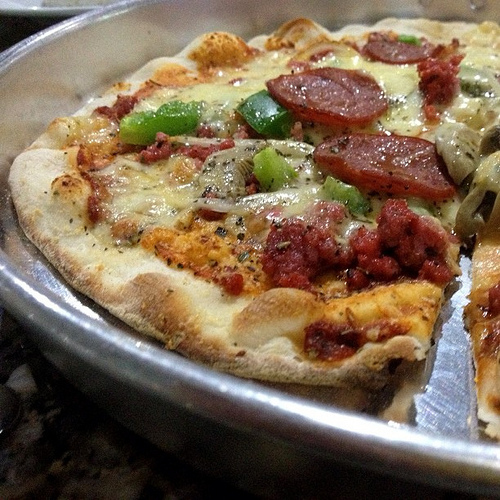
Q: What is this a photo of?
A: Pizza.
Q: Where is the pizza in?
A: Pan.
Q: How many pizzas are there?
A: 1.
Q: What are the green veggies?
A: Green peppers.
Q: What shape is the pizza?
A: Round.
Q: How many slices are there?
A: 4.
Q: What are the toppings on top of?
A: The crust.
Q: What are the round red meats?
A: Pepperonis.